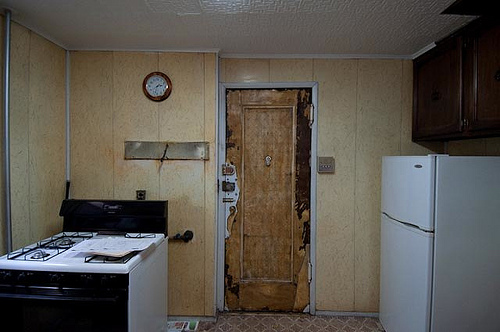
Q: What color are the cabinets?
A: Brown.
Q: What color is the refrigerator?
A: White.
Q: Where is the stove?
A: On the left.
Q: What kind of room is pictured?
A: A kitchen.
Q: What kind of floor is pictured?
A: Linoleum.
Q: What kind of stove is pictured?
A: A gas stove.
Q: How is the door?
A: Closed.